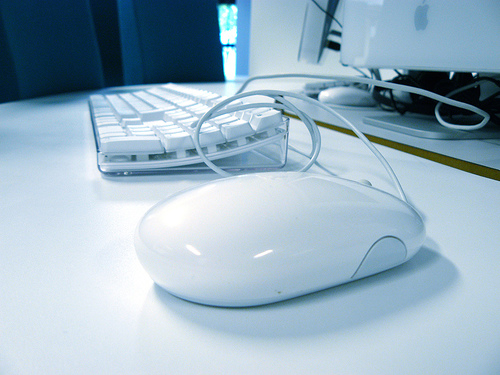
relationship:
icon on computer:
[406, 2, 433, 34] [335, 2, 499, 152]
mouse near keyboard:
[117, 157, 436, 328] [76, 75, 301, 178]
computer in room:
[335, 2, 499, 152] [2, 2, 499, 374]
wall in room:
[233, 1, 353, 78] [2, 2, 499, 374]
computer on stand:
[335, 2, 499, 152] [360, 103, 500, 148]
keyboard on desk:
[76, 75, 301, 178] [2, 73, 499, 374]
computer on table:
[335, 2, 499, 152] [2, 73, 499, 374]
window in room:
[219, 1, 240, 83] [2, 2, 499, 374]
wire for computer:
[188, 86, 419, 206] [335, 2, 499, 152]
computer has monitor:
[335, 2, 499, 152] [337, 1, 499, 82]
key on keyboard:
[98, 135, 164, 155] [76, 75, 301, 178]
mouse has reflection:
[117, 157, 436, 328] [183, 243, 204, 260]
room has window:
[2, 2, 499, 374] [219, 1, 240, 83]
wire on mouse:
[188, 86, 419, 206] [117, 157, 436, 328]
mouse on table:
[117, 157, 436, 328] [2, 73, 499, 374]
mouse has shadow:
[117, 157, 436, 328] [147, 242, 466, 344]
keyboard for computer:
[76, 75, 301, 178] [335, 2, 499, 152]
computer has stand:
[335, 2, 499, 152] [360, 103, 500, 148]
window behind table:
[219, 1, 240, 83] [2, 73, 499, 374]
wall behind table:
[233, 1, 353, 78] [2, 73, 499, 374]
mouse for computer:
[117, 157, 436, 328] [335, 2, 499, 152]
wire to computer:
[188, 86, 419, 206] [335, 2, 499, 152]